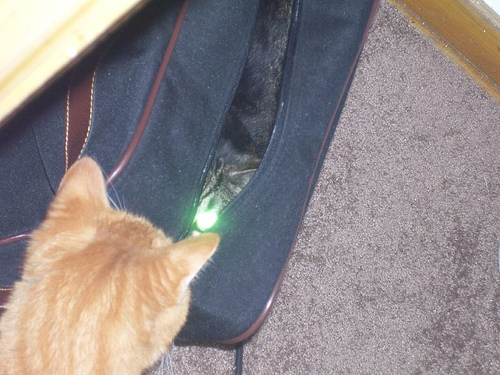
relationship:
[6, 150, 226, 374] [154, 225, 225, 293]
cat has a left ear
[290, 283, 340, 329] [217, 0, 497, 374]
patch on carpet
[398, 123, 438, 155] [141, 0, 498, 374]
patch on carpet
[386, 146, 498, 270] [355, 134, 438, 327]
patch of carpet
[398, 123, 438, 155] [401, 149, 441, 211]
patch of carpet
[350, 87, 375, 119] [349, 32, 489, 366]
brown patch of carpet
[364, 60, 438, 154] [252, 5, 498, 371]
patch of carpet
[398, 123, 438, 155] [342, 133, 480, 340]
patch of carpet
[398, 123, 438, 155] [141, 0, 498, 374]
patch of carpet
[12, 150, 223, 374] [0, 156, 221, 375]
head of cat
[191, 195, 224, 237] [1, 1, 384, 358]
light in case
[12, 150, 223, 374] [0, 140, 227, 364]
head of cat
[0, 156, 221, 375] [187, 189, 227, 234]
cat staring at light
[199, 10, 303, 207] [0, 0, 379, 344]
cat inside of bag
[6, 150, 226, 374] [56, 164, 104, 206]
cat has ear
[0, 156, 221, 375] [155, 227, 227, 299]
cat has ear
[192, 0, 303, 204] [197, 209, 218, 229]
cat has eye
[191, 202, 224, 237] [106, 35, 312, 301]
light on bag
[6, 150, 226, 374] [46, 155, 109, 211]
cat has ear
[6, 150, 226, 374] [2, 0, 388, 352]
cat looking at luggage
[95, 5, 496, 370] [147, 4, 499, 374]
carpet on floor